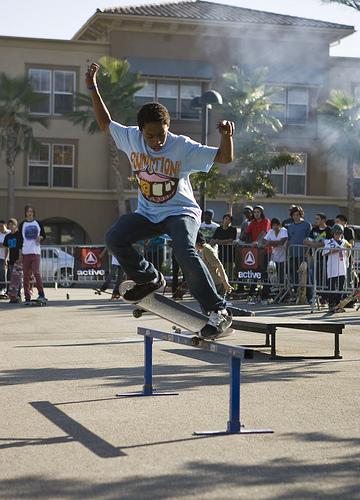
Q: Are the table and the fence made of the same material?
A: Yes, both the table and the fence are made of metal.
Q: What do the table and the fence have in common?
A: The material, both the table and the fence are metallic.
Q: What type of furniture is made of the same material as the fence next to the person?
A: The table is made of the same material as the fence.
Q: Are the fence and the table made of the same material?
A: Yes, both the fence and the table are made of metal.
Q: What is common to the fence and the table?
A: The material, both the fence and the table are metallic.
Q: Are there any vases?
A: No, there are no vases.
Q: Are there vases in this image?
A: No, there are no vases.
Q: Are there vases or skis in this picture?
A: No, there are no vases or skis.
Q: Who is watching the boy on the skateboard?
A: The crowd is watching the boy.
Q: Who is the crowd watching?
A: The crowd is watching the boy.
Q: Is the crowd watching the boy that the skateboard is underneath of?
A: Yes, the crowd is watching the boy.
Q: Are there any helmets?
A: No, there are no helmets.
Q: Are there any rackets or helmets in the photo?
A: No, there are no helmets or rackets.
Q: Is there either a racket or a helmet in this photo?
A: No, there are no helmets or rackets.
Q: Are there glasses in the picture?
A: No, there are no glasses.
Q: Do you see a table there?
A: Yes, there is a table.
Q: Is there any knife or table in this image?
A: Yes, there is a table.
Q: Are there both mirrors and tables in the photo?
A: No, there is a table but no mirrors.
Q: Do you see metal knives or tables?
A: Yes, there is a metal table.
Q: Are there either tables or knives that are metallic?
A: Yes, the table is metallic.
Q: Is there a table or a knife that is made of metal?
A: Yes, the table is made of metal.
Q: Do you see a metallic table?
A: Yes, there is a metal table.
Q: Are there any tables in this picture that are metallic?
A: Yes, there is a table that is metallic.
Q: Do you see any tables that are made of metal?
A: Yes, there is a table that is made of metal.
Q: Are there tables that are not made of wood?
A: Yes, there is a table that is made of metal.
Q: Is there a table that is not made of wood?
A: Yes, there is a table that is made of metal.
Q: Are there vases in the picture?
A: No, there are no vases.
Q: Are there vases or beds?
A: No, there are no vases or beds.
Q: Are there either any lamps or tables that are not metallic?
A: No, there is a table but it is metallic.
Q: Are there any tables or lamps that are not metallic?
A: No, there is a table but it is metallic.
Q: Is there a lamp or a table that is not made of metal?
A: No, there is a table but it is made of metal.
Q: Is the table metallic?
A: Yes, the table is metallic.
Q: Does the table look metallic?
A: Yes, the table is metallic.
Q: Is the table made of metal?
A: Yes, the table is made of metal.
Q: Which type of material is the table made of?
A: The table is made of metal.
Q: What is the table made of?
A: The table is made of metal.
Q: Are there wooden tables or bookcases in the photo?
A: No, there is a table but it is metallic.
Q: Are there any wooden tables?
A: No, there is a table but it is metallic.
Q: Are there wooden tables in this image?
A: No, there is a table but it is metallic.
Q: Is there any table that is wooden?
A: No, there is a table but it is metallic.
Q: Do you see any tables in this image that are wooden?
A: No, there is a table but it is metallic.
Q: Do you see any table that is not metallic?
A: No, there is a table but it is metallic.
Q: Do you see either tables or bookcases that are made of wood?
A: No, there is a table but it is made of metal.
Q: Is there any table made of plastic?
A: No, there is a table but it is made of metal.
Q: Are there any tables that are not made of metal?
A: No, there is a table but it is made of metal.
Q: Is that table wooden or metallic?
A: The table is metallic.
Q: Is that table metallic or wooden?
A: The table is metallic.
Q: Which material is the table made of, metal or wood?
A: The table is made of metal.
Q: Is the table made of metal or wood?
A: The table is made of metal.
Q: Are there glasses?
A: No, there are no glasses.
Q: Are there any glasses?
A: No, there are no glasses.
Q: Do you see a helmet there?
A: No, there are no helmets.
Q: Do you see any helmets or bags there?
A: No, there are no helmets or bags.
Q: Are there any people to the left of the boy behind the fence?
A: Yes, there is a person to the left of the boy.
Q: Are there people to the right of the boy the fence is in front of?
A: No, the person is to the left of the boy.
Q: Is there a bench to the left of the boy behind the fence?
A: No, there is a person to the left of the boy.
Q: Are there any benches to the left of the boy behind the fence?
A: No, there is a person to the left of the boy.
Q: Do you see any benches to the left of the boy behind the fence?
A: No, there is a person to the left of the boy.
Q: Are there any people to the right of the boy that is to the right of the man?
A: Yes, there is a person to the right of the boy.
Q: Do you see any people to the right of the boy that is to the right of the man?
A: Yes, there is a person to the right of the boy.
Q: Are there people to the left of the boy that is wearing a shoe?
A: No, the person is to the right of the boy.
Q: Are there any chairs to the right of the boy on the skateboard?
A: No, there is a person to the right of the boy.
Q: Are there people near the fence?
A: Yes, there is a person near the fence.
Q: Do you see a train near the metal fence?
A: No, there is a person near the fence.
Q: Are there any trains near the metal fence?
A: No, there is a person near the fence.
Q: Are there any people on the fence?
A: Yes, there is a person on the fence.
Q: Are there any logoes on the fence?
A: No, there is a person on the fence.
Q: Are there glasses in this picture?
A: No, there are no glasses.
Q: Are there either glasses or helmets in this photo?
A: No, there are no glasses or helmets.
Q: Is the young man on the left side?
A: Yes, the man is on the left of the image.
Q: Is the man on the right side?
A: No, the man is on the left of the image.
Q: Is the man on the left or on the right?
A: The man is on the left of the image.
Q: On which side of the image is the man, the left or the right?
A: The man is on the left of the image.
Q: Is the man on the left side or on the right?
A: The man is on the left of the image.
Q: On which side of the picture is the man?
A: The man is on the left of the image.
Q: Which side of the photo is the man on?
A: The man is on the left of the image.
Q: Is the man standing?
A: Yes, the man is standing.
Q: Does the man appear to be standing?
A: Yes, the man is standing.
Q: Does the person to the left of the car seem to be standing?
A: Yes, the man is standing.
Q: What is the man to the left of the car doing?
A: The man is standing.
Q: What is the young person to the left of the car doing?
A: The man is standing.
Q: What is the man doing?
A: The man is standing.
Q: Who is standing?
A: The man is standing.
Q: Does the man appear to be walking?
A: No, the man is standing.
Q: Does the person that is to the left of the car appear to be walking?
A: No, the man is standing.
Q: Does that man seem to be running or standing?
A: The man is standing.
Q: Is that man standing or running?
A: The man is standing.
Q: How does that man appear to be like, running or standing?
A: The man is standing.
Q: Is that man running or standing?
A: The man is standing.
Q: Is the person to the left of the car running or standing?
A: The man is standing.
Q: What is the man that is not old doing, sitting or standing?
A: The man is standing.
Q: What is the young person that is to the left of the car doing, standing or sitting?
A: The man is standing.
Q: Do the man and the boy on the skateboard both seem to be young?
A: Yes, both the man and the boy are young.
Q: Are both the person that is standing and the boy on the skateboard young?
A: Yes, both the man and the boy are young.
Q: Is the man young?
A: Yes, the man is young.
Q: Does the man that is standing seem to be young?
A: Yes, the man is young.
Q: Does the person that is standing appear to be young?
A: Yes, the man is young.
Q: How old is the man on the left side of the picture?
A: The man is young.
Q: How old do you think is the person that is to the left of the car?
A: The man is young.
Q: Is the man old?
A: No, the man is young.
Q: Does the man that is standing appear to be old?
A: No, the man is young.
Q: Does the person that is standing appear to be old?
A: No, the man is young.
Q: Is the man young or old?
A: The man is young.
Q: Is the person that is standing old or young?
A: The man is young.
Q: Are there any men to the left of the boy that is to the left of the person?
A: Yes, there is a man to the left of the boy.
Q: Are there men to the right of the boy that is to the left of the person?
A: No, the man is to the left of the boy.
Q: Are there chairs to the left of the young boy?
A: No, there is a man to the left of the boy.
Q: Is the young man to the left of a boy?
A: Yes, the man is to the left of a boy.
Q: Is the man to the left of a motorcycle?
A: No, the man is to the left of a boy.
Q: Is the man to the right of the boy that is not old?
A: No, the man is to the left of the boy.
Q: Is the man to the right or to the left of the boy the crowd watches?
A: The man is to the left of the boy.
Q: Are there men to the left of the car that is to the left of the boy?
A: Yes, there is a man to the left of the car.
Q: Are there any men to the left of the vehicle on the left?
A: Yes, there is a man to the left of the car.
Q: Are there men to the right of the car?
A: No, the man is to the left of the car.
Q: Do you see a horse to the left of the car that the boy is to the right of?
A: No, there is a man to the left of the car.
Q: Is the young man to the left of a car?
A: Yes, the man is to the left of a car.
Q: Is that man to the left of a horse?
A: No, the man is to the left of a car.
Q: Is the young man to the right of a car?
A: No, the man is to the left of a car.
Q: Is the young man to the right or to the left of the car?
A: The man is to the left of the car.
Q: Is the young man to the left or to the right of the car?
A: The man is to the left of the car.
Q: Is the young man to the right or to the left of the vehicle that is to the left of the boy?
A: The man is to the left of the car.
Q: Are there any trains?
A: No, there are no trains.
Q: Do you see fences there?
A: Yes, there is a fence.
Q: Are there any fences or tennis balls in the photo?
A: Yes, there is a fence.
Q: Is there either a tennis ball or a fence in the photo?
A: Yes, there is a fence.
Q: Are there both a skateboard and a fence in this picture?
A: Yes, there are both a fence and a skateboard.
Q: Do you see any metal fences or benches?
A: Yes, there is a metal fence.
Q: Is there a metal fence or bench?
A: Yes, there is a metal fence.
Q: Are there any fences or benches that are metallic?
A: Yes, the fence is metallic.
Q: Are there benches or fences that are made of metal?
A: Yes, the fence is made of metal.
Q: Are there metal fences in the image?
A: Yes, there is a metal fence.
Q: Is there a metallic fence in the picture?
A: Yes, there is a metal fence.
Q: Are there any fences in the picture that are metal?
A: Yes, there is a metal fence.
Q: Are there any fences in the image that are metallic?
A: Yes, there is a fence that is metallic.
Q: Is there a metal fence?
A: Yes, there is a fence that is made of metal.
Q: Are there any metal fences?
A: Yes, there is a fence that is made of metal.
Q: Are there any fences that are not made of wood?
A: Yes, there is a fence that is made of metal.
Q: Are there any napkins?
A: No, there are no napkins.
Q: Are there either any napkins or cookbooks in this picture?
A: No, there are no napkins or cookbooks.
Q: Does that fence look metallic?
A: Yes, the fence is metallic.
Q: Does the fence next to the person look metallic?
A: Yes, the fence is metallic.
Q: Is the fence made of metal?
A: Yes, the fence is made of metal.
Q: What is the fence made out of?
A: The fence is made of metal.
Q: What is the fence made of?
A: The fence is made of metal.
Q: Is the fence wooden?
A: No, the fence is metallic.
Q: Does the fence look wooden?
A: No, the fence is metallic.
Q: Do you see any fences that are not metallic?
A: No, there is a fence but it is metallic.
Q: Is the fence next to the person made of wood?
A: No, the fence is made of metal.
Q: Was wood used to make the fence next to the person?
A: No, the fence is made of metal.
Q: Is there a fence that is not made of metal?
A: No, there is a fence but it is made of metal.